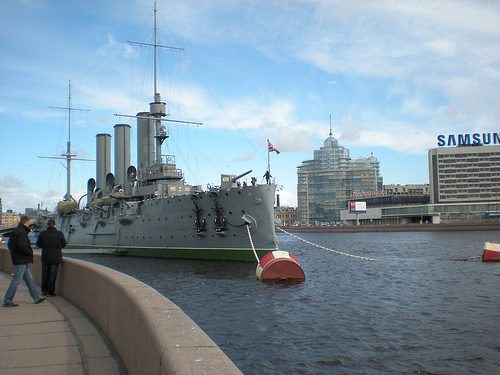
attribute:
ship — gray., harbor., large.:
[32, 39, 277, 266]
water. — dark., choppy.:
[205, 234, 497, 374]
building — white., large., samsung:
[427, 146, 500, 224]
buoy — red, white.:
[253, 248, 308, 283]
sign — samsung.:
[434, 132, 500, 145]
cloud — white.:
[208, 101, 300, 140]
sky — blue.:
[0, 2, 492, 136]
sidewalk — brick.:
[3, 309, 92, 371]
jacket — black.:
[37, 230, 68, 260]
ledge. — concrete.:
[62, 252, 234, 373]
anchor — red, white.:
[481, 240, 498, 262]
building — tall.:
[295, 114, 381, 221]